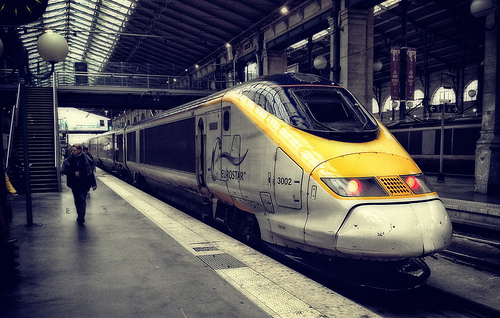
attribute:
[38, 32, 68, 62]
light — white, globe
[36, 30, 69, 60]
light — globe, white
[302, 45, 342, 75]
light — white, globe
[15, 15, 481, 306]
station — white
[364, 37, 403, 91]
light — globe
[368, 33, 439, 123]
flag — white, red, banner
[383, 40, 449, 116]
flag — banner, red, white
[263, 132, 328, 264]
door — small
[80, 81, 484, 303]
train — yellow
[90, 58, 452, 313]
train — yellow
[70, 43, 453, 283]
train — yellow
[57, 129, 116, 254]
person — walking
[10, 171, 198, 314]
platform — train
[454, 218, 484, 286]
tracks — part, train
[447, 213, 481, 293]
tracks — train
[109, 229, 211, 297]
platform — train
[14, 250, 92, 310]
platform — train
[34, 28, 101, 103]
light — hanging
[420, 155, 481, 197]
platform — hanging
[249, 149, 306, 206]
number — 3002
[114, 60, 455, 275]
train — yellow, white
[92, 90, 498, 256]
train — large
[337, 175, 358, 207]
headlight — orange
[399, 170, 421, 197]
headlight — orange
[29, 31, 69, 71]
light — white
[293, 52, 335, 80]
light — white